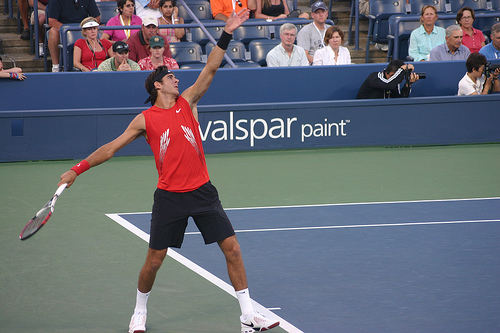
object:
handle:
[50, 183, 68, 201]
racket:
[19, 183, 68, 241]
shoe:
[240, 314, 280, 333]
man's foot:
[240, 313, 280, 332]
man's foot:
[128, 310, 147, 333]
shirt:
[266, 43, 310, 67]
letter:
[197, 121, 212, 142]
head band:
[144, 71, 173, 107]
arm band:
[217, 30, 232, 50]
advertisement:
[199, 111, 351, 147]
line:
[186, 219, 500, 235]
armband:
[71, 160, 90, 176]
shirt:
[137, 55, 179, 71]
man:
[97, 41, 142, 72]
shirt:
[74, 38, 113, 71]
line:
[117, 196, 500, 216]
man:
[56, 7, 280, 333]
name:
[197, 111, 348, 146]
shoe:
[128, 312, 148, 332]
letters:
[211, 120, 227, 142]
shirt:
[98, 57, 142, 71]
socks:
[235, 287, 256, 320]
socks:
[134, 287, 151, 314]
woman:
[73, 16, 115, 72]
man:
[356, 60, 419, 99]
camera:
[405, 69, 426, 81]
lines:
[104, 213, 303, 333]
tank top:
[142, 95, 210, 193]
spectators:
[137, 36, 179, 71]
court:
[0, 143, 500, 332]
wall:
[336, 110, 481, 129]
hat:
[149, 35, 165, 47]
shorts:
[148, 180, 235, 251]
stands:
[0, 2, 500, 162]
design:
[158, 125, 204, 176]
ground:
[328, 183, 498, 332]